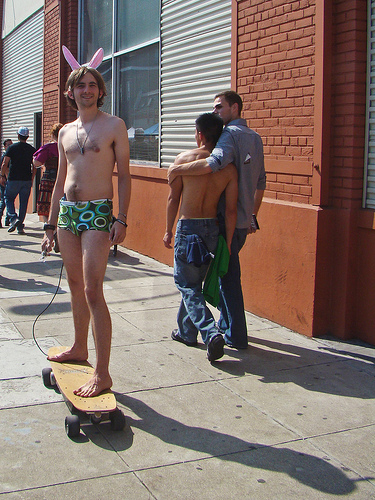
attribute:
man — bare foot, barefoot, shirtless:
[39, 45, 131, 439]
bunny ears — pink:
[61, 41, 106, 71]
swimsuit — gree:
[56, 195, 112, 236]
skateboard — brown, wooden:
[42, 346, 126, 438]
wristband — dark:
[116, 217, 128, 227]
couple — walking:
[163, 88, 269, 361]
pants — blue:
[172, 218, 225, 360]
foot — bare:
[44, 349, 114, 397]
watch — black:
[42, 222, 56, 232]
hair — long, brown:
[64, 67, 109, 108]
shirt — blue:
[204, 116, 266, 230]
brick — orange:
[43, 1, 372, 338]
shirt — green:
[202, 234, 229, 311]